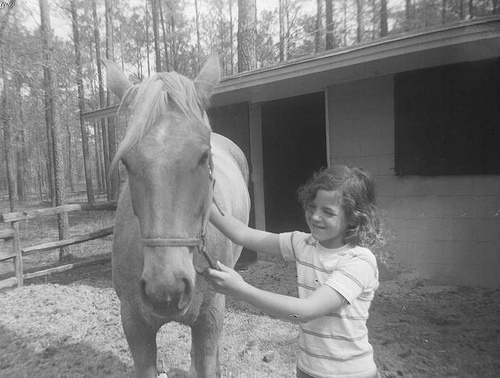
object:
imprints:
[102, 287, 116, 307]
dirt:
[453, 291, 490, 307]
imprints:
[254, 324, 268, 349]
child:
[210, 161, 393, 377]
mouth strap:
[132, 237, 215, 274]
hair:
[100, 66, 205, 158]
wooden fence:
[0, 206, 116, 293]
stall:
[252, 91, 324, 250]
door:
[260, 91, 326, 237]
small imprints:
[392, 288, 423, 314]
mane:
[104, 68, 206, 179]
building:
[207, 15, 499, 293]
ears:
[103, 55, 136, 104]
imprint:
[253, 337, 276, 352]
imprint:
[380, 335, 410, 357]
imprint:
[436, 309, 465, 326]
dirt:
[55, 255, 103, 295]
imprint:
[82, 325, 98, 338]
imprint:
[43, 353, 63, 370]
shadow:
[1, 320, 133, 376]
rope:
[201, 175, 217, 239]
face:
[119, 68, 216, 317]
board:
[387, 59, 499, 187]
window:
[378, 58, 499, 182]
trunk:
[41, 1, 70, 267]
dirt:
[401, 355, 434, 376]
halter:
[142, 235, 222, 275]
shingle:
[385, 180, 497, 275]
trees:
[315, 0, 327, 58]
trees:
[43, 3, 74, 262]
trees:
[90, 0, 103, 198]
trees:
[0, 70, 20, 210]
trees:
[40, 3, 56, 199]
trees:
[152, 2, 160, 70]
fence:
[2, 197, 120, 287]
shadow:
[380, 271, 437, 298]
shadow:
[39, 244, 118, 289]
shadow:
[384, 295, 496, 376]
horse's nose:
[136, 273, 199, 321]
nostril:
[174, 276, 198, 306]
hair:
[296, 161, 391, 252]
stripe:
[295, 254, 334, 274]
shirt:
[277, 230, 379, 377]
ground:
[0, 202, 499, 378]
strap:
[140, 235, 201, 247]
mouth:
[139, 226, 192, 318]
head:
[93, 43, 225, 318]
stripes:
[298, 349, 374, 365]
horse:
[99, 49, 252, 375]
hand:
[204, 260, 244, 297]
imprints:
[7, 302, 19, 319]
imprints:
[470, 285, 488, 294]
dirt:
[10, 326, 38, 349]